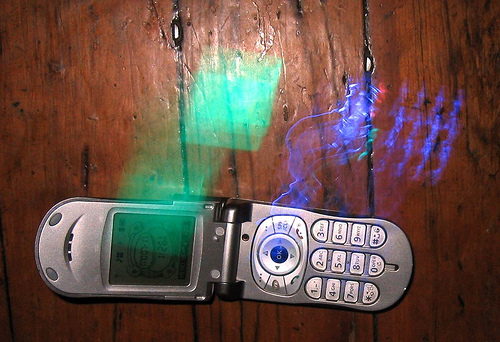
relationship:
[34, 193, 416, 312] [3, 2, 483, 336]
cellphone on table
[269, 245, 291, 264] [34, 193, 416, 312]
cellphone button on cellphone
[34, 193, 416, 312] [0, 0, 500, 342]
cellphone lying on table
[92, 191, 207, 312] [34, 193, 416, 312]
cellphone screen built into cellphone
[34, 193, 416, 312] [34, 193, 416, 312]
cellphone belonging to cellphone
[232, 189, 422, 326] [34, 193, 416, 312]
cellphone bottom belonging to cellphone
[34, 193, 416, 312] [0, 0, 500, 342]
cellphone sitting on top of table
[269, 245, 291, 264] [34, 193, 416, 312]
cellphone button built into cellphone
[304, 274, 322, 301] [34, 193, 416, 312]
number button built into cellphone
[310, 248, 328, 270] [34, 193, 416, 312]
button built into cellphone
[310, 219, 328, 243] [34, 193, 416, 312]
button light built into cellphone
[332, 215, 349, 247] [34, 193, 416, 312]
number button built into cellphone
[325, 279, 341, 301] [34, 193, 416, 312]
number button built into cellphone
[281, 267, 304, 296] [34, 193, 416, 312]
answer button built into cellphone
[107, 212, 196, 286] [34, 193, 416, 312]
cellphone screen built into cellphone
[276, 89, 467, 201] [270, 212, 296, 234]
blur created by button light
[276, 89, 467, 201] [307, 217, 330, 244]
blur created by button light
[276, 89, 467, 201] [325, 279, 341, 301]
blur created by number button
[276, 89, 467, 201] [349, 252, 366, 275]
blur created by button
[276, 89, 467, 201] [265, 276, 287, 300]
blur created by phone buttons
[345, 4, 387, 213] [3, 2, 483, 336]
crack appearing in table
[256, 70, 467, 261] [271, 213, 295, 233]
blur created by button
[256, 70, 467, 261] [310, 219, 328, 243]
blur created by button light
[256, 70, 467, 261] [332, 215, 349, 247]
blur created by number button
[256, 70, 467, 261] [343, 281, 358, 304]
blur created by button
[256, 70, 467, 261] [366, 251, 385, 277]
blur created by button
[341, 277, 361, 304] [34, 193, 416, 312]
button built into cellphone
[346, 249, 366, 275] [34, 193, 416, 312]
button built into cellphone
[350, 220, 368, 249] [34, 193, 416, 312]
button built into cellphone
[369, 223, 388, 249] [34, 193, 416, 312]
button built into cellphone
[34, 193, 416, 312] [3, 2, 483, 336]
cellphone sitting on top of table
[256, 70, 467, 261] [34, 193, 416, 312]
blur from cellphone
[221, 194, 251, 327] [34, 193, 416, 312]
hinge on cellphone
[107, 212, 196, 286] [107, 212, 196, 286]
cellphone screen on cellphone screen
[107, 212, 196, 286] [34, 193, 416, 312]
cellphone screen on cellphone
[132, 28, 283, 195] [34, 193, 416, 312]
green reflection on cellphone